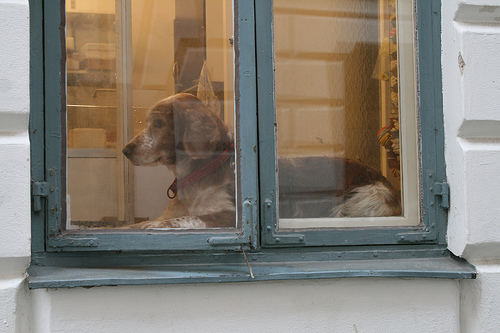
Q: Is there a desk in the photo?
A: No, there are no desks.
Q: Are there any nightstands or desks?
A: No, there are no desks or nightstands.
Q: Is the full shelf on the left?
A: Yes, the shelf is on the left of the image.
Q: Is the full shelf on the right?
A: No, the shelf is on the left of the image.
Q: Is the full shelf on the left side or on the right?
A: The shelf is on the left of the image.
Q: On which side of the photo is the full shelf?
A: The shelf is on the left of the image.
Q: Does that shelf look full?
A: Yes, the shelf is full.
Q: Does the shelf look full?
A: Yes, the shelf is full.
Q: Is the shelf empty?
A: No, the shelf is full.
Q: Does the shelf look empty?
A: No, the shelf is full.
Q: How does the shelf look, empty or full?
A: The shelf is full.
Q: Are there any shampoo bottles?
A: No, there are no shampoo bottles.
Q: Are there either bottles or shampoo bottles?
A: No, there are no shampoo bottles or bottles.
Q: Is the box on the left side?
A: Yes, the box is on the left of the image.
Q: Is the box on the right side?
A: No, the box is on the left of the image.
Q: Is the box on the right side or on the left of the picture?
A: The box is on the left of the image.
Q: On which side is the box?
A: The box is on the left of the image.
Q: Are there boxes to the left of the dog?
A: Yes, there is a box to the left of the dog.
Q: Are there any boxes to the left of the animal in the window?
A: Yes, there is a box to the left of the dog.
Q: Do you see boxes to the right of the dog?
A: No, the box is to the left of the dog.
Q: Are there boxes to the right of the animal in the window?
A: No, the box is to the left of the dog.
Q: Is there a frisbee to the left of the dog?
A: No, there is a box to the left of the dog.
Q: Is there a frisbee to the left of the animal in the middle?
A: No, there is a box to the left of the dog.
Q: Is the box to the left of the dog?
A: Yes, the box is to the left of the dog.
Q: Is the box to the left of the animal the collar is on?
A: Yes, the box is to the left of the dog.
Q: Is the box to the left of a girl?
A: No, the box is to the left of the dog.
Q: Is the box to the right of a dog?
A: No, the box is to the left of a dog.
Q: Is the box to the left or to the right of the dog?
A: The box is to the left of the dog.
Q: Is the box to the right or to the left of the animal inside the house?
A: The box is to the left of the dog.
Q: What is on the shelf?
A: The box is on the shelf.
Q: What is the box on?
A: The box is on the shelf.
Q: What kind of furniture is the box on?
A: The box is on the shelf.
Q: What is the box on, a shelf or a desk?
A: The box is on a shelf.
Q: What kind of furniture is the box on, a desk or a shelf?
A: The box is on a shelf.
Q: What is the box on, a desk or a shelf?
A: The box is on a shelf.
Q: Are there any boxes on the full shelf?
A: Yes, there is a box on the shelf.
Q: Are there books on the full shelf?
A: No, there is a box on the shelf.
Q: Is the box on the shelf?
A: Yes, the box is on the shelf.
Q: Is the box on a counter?
A: No, the box is on the shelf.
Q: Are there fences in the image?
A: No, there are no fences.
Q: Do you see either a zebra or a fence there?
A: No, there are no fences or zebras.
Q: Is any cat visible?
A: No, there are no cats.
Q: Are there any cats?
A: No, there are no cats.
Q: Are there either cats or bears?
A: No, there are no cats or bears.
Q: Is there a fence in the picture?
A: No, there are no fences.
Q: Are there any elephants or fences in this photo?
A: No, there are no fences or elephants.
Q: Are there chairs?
A: No, there are no chairs.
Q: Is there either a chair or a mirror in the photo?
A: No, there are no chairs or mirrors.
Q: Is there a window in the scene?
A: Yes, there is a window.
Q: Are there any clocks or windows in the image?
A: Yes, there is a window.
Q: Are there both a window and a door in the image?
A: No, there is a window but no doors.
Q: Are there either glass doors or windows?
A: Yes, there is a glass window.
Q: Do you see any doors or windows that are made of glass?
A: Yes, the window is made of glass.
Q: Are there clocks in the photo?
A: No, there are no clocks.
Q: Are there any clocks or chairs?
A: No, there are no clocks or chairs.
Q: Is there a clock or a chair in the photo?
A: No, there are no clocks or chairs.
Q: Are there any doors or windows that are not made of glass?
A: No, there is a window but it is made of glass.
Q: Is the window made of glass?
A: Yes, the window is made of glass.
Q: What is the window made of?
A: The window is made of glass.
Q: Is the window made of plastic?
A: No, the window is made of glass.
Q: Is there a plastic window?
A: No, there is a window but it is made of glass.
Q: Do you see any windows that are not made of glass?
A: No, there is a window but it is made of glass.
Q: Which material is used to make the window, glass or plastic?
A: The window is made of glass.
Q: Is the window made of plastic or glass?
A: The window is made of glass.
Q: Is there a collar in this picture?
A: Yes, there is a collar.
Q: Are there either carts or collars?
A: Yes, there is a collar.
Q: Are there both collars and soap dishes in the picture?
A: No, there is a collar but no soap dishes.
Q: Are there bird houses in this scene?
A: No, there are no bird houses.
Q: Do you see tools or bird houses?
A: No, there are no bird houses or tools.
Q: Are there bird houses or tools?
A: No, there are no bird houses or tools.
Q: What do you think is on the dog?
A: The collar is on the dog.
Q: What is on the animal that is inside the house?
A: The collar is on the dog.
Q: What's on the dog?
A: The collar is on the dog.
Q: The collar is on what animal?
A: The collar is on the dog.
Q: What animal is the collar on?
A: The collar is on the dog.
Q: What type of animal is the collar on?
A: The collar is on the dog.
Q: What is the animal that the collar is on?
A: The animal is a dog.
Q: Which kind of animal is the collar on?
A: The collar is on the dog.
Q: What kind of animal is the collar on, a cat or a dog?
A: The collar is on a dog.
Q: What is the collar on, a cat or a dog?
A: The collar is on a dog.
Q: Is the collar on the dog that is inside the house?
A: Yes, the collar is on the dog.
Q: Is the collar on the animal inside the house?
A: Yes, the collar is on the dog.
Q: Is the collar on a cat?
A: No, the collar is on the dog.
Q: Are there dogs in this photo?
A: Yes, there is a dog.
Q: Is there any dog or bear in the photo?
A: Yes, there is a dog.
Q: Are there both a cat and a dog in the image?
A: No, there is a dog but no cats.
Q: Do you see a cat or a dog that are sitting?
A: Yes, the dog is sitting.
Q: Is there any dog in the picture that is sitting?
A: Yes, there is a dog that is sitting.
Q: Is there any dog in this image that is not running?
A: Yes, there is a dog that is sitting.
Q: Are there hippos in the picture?
A: No, there are no hippos.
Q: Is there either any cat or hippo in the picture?
A: No, there are no hippos or cats.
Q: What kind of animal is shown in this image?
A: The animal is a dog.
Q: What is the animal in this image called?
A: The animal is a dog.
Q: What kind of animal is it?
A: The animal is a dog.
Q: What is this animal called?
A: This is a dog.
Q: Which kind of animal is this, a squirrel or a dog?
A: This is a dog.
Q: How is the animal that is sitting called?
A: The animal is a dog.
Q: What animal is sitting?
A: The animal is a dog.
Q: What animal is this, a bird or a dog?
A: This is a dog.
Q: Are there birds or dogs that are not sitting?
A: No, there is a dog but it is sitting.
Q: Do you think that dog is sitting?
A: Yes, the dog is sitting.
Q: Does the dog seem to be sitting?
A: Yes, the dog is sitting.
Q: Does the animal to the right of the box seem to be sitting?
A: Yes, the dog is sitting.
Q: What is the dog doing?
A: The dog is sitting.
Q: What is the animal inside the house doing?
A: The dog is sitting.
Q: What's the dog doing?
A: The dog is sitting.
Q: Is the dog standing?
A: No, the dog is sitting.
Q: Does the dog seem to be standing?
A: No, the dog is sitting.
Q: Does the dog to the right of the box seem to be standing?
A: No, the dog is sitting.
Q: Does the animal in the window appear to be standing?
A: No, the dog is sitting.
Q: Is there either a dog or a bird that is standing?
A: No, there is a dog but it is sitting.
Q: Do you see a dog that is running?
A: No, there is a dog but it is sitting.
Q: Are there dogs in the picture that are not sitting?
A: No, there is a dog but it is sitting.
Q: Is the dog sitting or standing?
A: The dog is sitting.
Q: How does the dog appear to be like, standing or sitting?
A: The dog is sitting.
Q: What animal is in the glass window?
A: The dog is in the window.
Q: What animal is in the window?
A: The dog is in the window.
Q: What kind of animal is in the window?
A: The animal is a dog.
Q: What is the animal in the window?
A: The animal is a dog.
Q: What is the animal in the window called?
A: The animal is a dog.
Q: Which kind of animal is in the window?
A: The animal is a dog.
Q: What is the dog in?
A: The dog is in the window.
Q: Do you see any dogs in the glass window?
A: Yes, there is a dog in the window.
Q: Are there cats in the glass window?
A: No, there is a dog in the window.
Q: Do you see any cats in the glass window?
A: No, there is a dog in the window.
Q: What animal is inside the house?
A: The dog is inside the house.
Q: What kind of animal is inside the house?
A: The animal is a dog.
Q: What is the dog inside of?
A: The dog is inside the house.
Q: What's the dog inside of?
A: The dog is inside the house.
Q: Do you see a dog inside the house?
A: Yes, there is a dog inside the house.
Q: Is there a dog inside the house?
A: Yes, there is a dog inside the house.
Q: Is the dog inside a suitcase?
A: No, the dog is inside the house.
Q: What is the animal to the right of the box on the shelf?
A: The animal is a dog.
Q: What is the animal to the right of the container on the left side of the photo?
A: The animal is a dog.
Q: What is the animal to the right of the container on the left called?
A: The animal is a dog.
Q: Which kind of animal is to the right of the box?
A: The animal is a dog.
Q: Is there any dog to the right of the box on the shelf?
A: Yes, there is a dog to the right of the box.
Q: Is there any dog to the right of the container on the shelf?
A: Yes, there is a dog to the right of the box.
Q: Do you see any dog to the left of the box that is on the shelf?
A: No, the dog is to the right of the box.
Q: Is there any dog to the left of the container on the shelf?
A: No, the dog is to the right of the box.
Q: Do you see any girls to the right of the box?
A: No, there is a dog to the right of the box.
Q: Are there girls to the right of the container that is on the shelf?
A: No, there is a dog to the right of the box.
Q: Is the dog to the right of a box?
A: Yes, the dog is to the right of a box.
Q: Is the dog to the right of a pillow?
A: No, the dog is to the right of a box.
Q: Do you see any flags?
A: No, there are no flags.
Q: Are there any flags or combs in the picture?
A: No, there are no flags or combs.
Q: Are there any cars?
A: No, there are no cars.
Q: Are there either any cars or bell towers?
A: No, there are no cars or bell towers.